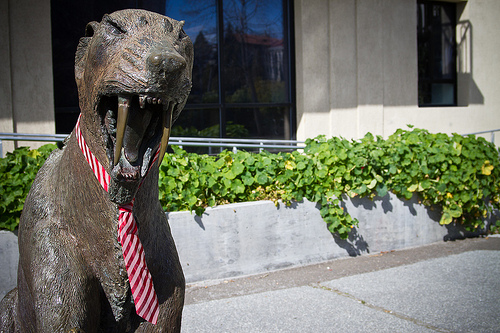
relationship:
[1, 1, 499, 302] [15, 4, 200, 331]
building behind sculpture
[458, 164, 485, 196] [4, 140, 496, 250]
leaves on plants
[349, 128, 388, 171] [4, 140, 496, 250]
leaves on plants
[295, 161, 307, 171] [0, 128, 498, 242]
leaves on plants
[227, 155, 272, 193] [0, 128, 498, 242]
leaves on plants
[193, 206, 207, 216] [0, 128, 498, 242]
leaves on plants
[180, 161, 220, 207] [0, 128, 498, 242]
leaves on plants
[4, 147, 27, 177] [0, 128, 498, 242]
leaves on plants